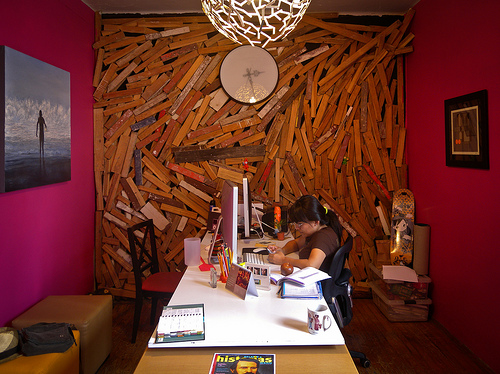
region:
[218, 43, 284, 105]
A round wall clock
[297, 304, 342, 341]
A white coffee cup with a design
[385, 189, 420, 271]
A skateboard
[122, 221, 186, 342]
A black chair with a red seat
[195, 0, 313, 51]
A light fixture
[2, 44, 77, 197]
A wall photo of a person on the beach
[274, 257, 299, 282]
A red apple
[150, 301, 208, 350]
An open appointment book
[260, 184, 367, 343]
A person sitting in a black chair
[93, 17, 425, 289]
A wall of strips of wood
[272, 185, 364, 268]
a woman sitting at a desk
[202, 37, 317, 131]
white clock on the wall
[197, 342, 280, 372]
a magazine on the wall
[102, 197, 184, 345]
a black and red chair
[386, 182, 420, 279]
a board in the corner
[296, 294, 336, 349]
a white coffee cup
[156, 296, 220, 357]
a white planner on the desk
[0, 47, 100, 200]
a piece of artwork on the wall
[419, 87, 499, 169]
art with a black frame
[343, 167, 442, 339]
a pile of clutter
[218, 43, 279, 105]
round white clock hanging on wall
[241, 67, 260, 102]
gray minute hand on clock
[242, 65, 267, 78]
gray hour hand on clock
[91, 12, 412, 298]
wall constructed of planks of wood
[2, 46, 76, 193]
picture hanging on purple wall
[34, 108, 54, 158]
person standing in picture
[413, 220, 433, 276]
brown cardboard tube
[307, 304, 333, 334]
mug on table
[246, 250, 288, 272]
white keyboard on table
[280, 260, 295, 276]
red apple on table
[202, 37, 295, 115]
numberless analog clock on the wall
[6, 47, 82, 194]
painting of an ocean scene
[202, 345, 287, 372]
magazine with a man on the cover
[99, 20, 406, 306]
artistic wall made of pieces of wood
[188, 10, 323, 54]
modern art style overhead light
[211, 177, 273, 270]
Apple desktop computer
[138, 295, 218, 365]
open notebook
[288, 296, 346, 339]
white ceramic coffee mug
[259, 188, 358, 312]
woman looking at her phone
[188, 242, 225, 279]
red flyswatter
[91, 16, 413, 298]
wall covered with boards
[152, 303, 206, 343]
engagement calendar open on desk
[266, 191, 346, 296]
girl working at desk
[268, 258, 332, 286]
open book with an apple on it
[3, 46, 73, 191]
painting of a solitary person on the beach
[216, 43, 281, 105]
round wall clock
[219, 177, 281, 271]
computer screen and keyboard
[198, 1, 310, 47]
modernistic ceiling light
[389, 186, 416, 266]
skateboard leaning against the wall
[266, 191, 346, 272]
girl's hair tied in a ponytail